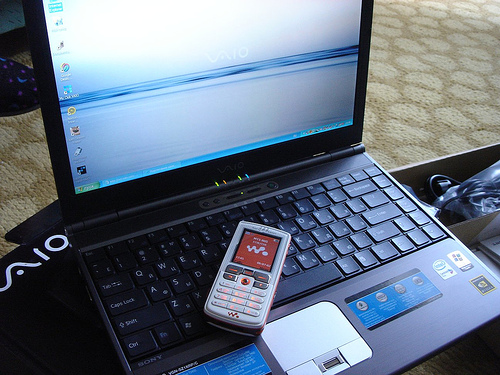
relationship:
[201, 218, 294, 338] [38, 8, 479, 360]
cellphone sitting on laptop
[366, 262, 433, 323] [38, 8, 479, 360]
sticker applied to laptop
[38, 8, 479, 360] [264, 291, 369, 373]
laptop sitting on mouse pad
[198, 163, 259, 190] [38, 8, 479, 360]
lights on laptop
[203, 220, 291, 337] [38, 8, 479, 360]
cellphone on laptop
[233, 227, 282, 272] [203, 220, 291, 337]
logo on cellphone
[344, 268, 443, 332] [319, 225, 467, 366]
sticker on laptop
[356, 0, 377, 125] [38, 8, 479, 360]
edge on laptop